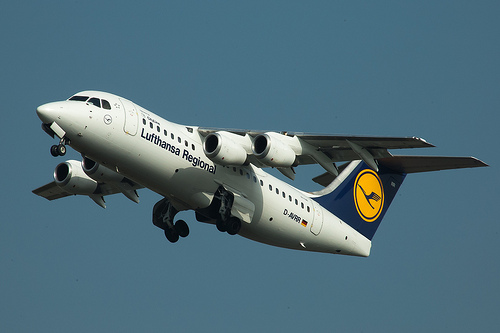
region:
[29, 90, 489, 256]
the plane is airborne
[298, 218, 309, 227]
it has a german flag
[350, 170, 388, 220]
a yellow picture at the back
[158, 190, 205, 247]
it wheels are folding back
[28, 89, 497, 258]
the plane is taking off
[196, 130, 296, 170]
the plane has a double engine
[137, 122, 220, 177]
it has some writtings on the body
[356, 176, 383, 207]
it has a picture of a bird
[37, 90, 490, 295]
the plane is white in colour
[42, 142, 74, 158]
it has two wheels at the front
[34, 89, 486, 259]
plane flying in air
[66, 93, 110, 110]
glass cock pit windows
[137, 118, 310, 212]
windows on side of plane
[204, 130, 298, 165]
booster jets on plane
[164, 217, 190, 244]
black tires on plane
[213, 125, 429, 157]
wing on side of plane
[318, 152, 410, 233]
tail on back of plane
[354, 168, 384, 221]
yellow decal on plane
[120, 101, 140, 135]
white door on plane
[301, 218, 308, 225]
german flag on plane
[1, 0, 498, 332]
A clear blue sky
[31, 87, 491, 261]
A large blue and white airplane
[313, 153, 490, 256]
The tail wing of a plane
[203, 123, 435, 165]
the left wing of a plane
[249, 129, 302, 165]
an engine on the left wing of the plane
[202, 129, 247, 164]
an engine on the left wing of the plane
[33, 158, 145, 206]
the right wing of a plane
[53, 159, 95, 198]
an engine on the right wing of the plane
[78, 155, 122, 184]
an engine on the right wing of the plane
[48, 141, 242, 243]
the landing gear of the plane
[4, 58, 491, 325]
plane is in air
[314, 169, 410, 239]
plane has blue tail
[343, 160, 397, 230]
yellow logo on tail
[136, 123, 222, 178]
blue letters on plane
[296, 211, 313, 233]
German flag on plane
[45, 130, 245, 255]
plane's wheels are out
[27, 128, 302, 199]
2 engines on each side of plane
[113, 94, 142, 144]
plane door is closed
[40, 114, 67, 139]
doors open on bottom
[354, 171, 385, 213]
bird on the logo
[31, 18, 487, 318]
plane flying against blue-gray sky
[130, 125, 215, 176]
dark writing on plane body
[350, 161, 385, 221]
yellow circle with yellow ring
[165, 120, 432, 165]
wing attached to top of plane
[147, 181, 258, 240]
curved covers on sides of lifted wheels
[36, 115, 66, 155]
open flaps above wheels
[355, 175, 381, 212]
symbol made with dark curved lines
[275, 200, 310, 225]
identifying code and flag on plane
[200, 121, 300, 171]
white engines with silver openings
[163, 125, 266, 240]
shadow over middle of plane